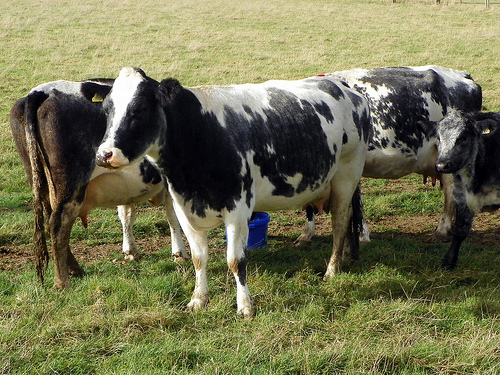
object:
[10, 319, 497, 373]
field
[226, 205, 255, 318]
leg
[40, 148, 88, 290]
leg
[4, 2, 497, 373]
ground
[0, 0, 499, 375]
green field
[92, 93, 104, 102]
tag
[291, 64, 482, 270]
cow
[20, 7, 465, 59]
field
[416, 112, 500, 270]
cow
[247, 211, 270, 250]
bucket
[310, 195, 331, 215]
udder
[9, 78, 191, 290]
cow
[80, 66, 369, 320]
cows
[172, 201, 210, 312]
front legs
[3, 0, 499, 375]
grass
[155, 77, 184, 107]
ear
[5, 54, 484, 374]
camera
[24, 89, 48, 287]
tail